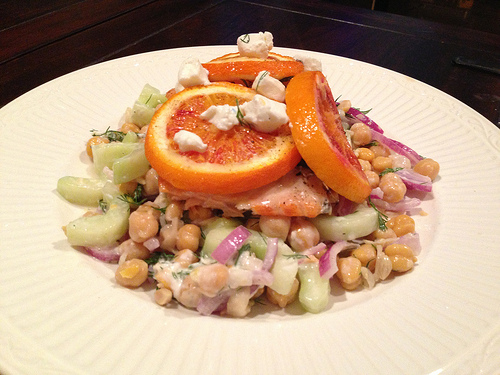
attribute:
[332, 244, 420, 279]
peas — white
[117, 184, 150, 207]
herb — green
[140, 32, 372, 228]
toppings — white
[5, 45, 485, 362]
food/white plate — white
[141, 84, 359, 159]
cheese — blue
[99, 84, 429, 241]
food — creamy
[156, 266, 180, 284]
creamy substance — white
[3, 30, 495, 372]
white plate — white 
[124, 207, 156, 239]
bean — brown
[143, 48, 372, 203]
oranges — orange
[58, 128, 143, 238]
cucumber — light green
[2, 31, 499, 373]
plate — white, round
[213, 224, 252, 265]
onions — raw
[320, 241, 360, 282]
onions — raw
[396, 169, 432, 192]
onions — raw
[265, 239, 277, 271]
onions — raw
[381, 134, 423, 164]
onion — purple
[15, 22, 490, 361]
plate — white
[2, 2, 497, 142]
table — brown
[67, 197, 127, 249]
celery — green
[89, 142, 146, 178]
celery — green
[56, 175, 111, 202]
celery — green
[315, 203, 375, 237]
celery — green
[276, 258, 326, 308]
celery — green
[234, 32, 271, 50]
cheese — small, white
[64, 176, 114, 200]
cucumber slices — green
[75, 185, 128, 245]
cucumber slices — green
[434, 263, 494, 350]
plate — white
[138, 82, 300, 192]
orange — sliced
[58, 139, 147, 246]
chopped cucumbers — green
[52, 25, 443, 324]
food — served, delicious, brown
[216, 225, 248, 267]
onion piece — chopped, small, red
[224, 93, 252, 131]
herb — green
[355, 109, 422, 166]
onion — red, sliced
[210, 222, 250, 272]
onion — sliver, purple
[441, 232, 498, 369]
plate — white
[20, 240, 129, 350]
plate — white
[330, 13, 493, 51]
surface — wooden, dark